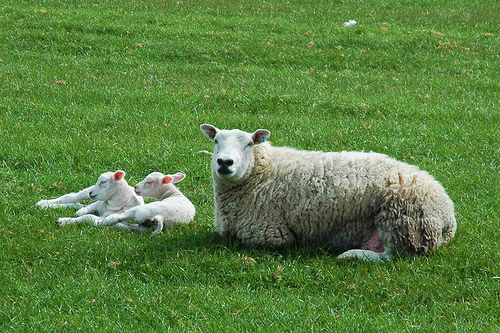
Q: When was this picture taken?
A: Spring.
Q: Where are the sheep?
A: In the grass.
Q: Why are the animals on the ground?
A: Resting.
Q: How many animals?
A: Three.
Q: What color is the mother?
A: White.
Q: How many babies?
A: Two.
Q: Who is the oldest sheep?
A: The mother.